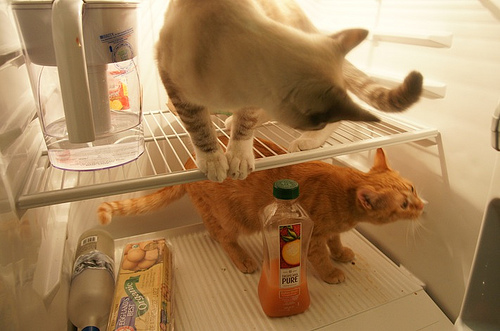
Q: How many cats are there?
A: Two.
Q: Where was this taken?
A: In a kitchen.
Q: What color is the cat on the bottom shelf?
A: Orange and white.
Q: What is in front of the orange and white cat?
A: Juice.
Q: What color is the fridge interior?
A: White.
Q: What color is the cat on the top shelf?
A: White and gray.